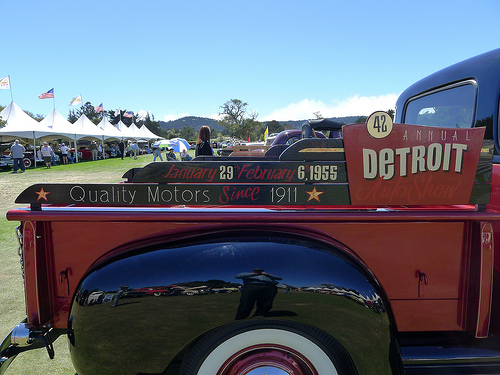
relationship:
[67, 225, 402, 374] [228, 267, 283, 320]
fender showing reflection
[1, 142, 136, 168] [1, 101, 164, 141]
antique cars under tents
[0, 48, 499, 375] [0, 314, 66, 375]
truck has bumper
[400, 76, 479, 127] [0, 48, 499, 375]
window behind truck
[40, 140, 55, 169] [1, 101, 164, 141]
man passing tents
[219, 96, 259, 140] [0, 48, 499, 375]
tree behind truck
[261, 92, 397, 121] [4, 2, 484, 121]
clouds in front of sky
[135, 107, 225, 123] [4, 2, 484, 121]
clouds in front of sky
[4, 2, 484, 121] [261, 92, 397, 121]
sky behind clouds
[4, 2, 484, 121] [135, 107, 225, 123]
sky behind clouds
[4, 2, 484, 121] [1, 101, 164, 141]
sky behind tents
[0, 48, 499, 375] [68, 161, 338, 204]
truck has words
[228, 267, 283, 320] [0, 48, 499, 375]
reflection in front of truck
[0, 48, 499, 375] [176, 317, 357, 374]
truck has tire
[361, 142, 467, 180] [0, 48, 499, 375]
detroit printed on truck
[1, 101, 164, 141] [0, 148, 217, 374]
tents standing on ground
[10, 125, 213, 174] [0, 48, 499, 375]
people behind truck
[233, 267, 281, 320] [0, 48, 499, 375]
man reflection from truck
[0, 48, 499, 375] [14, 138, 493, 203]
truck has wood railing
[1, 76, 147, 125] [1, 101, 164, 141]
flags on top of tents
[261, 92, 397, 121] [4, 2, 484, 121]
clouds in sky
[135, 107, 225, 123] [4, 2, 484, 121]
clouds in sky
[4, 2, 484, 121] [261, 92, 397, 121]
sky containing clouds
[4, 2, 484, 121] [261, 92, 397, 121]
sky has clouds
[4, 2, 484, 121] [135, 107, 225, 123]
sky has clouds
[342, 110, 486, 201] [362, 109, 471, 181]
sign contains gold and white